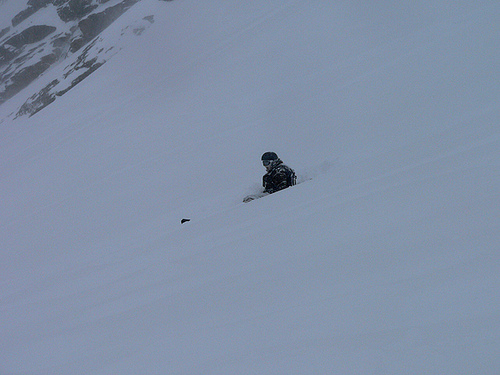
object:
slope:
[78, 41, 436, 361]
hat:
[259, 151, 280, 162]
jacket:
[258, 165, 300, 194]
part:
[435, 247, 452, 266]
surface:
[381, 264, 484, 356]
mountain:
[0, 0, 500, 373]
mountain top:
[0, 0, 500, 120]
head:
[258, 150, 281, 168]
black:
[265, 174, 283, 185]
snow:
[0, 0, 500, 373]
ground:
[1, 0, 500, 373]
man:
[238, 148, 301, 203]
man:
[178, 148, 300, 227]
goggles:
[259, 159, 275, 166]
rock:
[11, 12, 157, 125]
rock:
[1, 1, 140, 105]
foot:
[180, 215, 193, 227]